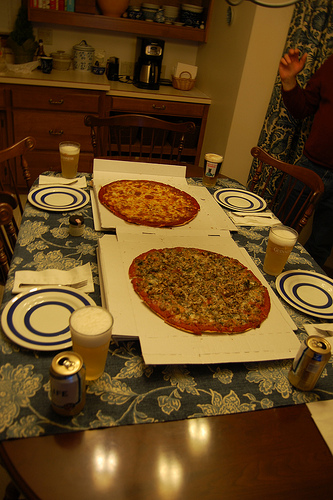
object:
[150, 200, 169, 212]
cheese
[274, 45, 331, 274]
person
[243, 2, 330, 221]
curtain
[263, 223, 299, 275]
beer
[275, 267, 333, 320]
plate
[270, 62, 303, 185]
curtain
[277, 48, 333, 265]
guy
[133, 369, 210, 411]
cloth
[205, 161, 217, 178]
design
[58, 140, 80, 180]
beer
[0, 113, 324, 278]
chairs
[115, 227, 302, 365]
box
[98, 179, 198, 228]
pizza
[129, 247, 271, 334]
pizza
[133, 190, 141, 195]
pepperoni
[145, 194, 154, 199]
pepperoni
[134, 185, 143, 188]
pepperoni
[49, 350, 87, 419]
can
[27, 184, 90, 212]
plate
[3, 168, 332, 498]
table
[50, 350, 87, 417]
open can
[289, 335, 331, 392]
open can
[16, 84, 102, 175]
drawers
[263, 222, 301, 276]
cup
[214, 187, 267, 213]
plate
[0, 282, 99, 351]
plate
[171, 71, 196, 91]
basket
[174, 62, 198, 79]
paper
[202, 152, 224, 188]
glass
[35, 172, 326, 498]
table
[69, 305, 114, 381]
glass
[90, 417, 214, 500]
lamps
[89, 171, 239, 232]
box